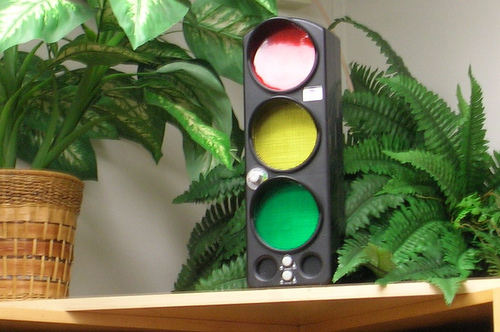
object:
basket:
[1, 167, 84, 299]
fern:
[169, 17, 496, 305]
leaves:
[2, 0, 279, 182]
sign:
[244, 96, 318, 172]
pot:
[1, 164, 90, 301]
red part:
[248, 21, 318, 95]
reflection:
[241, 37, 335, 101]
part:
[250, 179, 320, 256]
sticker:
[291, 87, 341, 110]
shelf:
[0, 273, 500, 326]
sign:
[250, 175, 322, 251]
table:
[0, 277, 500, 327]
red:
[241, 16, 325, 94]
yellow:
[244, 93, 319, 173]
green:
[248, 175, 321, 254]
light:
[240, 15, 338, 287]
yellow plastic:
[253, 101, 318, 169]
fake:
[245, 15, 344, 284]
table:
[241, 14, 339, 289]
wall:
[64, 208, 169, 291]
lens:
[250, 103, 319, 172]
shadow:
[82, 154, 185, 285]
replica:
[241, 18, 341, 283]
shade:
[243, 18, 320, 89]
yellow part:
[248, 103, 318, 172]